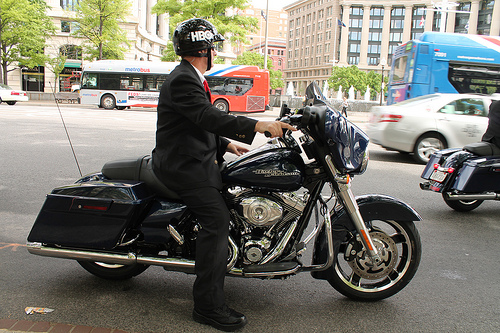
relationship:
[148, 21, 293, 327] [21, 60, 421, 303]
man on motorcycle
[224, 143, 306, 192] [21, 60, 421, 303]
tank on motorcycle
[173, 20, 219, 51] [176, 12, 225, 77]
helmet on head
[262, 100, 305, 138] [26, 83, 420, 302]
handlebar on motorcycle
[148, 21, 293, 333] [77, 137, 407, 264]
man on motorcycle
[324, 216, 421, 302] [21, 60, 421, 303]
front wheel on motorcycle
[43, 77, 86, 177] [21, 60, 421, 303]
antenna on motorcycle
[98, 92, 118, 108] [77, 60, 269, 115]
wheel on bus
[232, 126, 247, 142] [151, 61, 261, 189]
buttons on coat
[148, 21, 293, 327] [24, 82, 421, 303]
man on bike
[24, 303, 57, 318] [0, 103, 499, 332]
trash on ground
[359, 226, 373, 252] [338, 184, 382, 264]
orange reflector on metal piece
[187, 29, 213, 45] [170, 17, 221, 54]
white writing on helmet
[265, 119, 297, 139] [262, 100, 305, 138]
fingers on handlebar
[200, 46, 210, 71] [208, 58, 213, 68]
strap under chin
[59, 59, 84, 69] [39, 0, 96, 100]
green awning attached to building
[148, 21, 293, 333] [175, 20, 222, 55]
man wearing helmet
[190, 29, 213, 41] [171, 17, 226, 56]
lettering on helmet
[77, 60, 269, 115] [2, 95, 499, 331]
bus on street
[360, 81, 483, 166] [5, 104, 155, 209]
silver car driving on road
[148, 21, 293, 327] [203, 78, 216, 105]
man wearing necktie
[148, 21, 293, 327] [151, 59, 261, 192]
man wearing coat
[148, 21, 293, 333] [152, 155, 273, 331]
man wearing dress pants